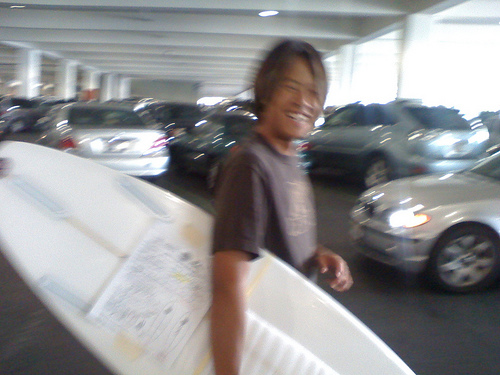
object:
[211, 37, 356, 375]
surfer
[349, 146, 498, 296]
car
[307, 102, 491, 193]
car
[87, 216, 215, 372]
paper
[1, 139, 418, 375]
surfboard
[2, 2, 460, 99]
roof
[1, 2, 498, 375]
garage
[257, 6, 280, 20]
light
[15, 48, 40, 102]
column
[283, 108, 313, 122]
smile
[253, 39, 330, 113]
hair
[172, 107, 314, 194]
vehicle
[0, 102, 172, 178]
car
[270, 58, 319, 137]
face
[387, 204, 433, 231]
headlight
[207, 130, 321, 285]
shirt